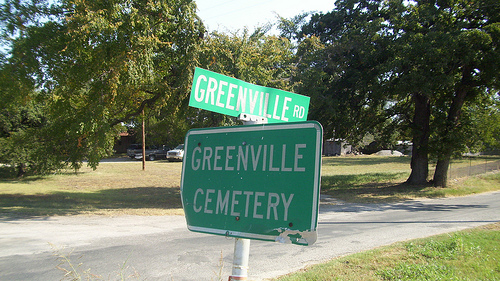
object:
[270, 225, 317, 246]
paint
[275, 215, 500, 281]
grassy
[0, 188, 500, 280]
sidewalk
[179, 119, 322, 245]
sign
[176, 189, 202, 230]
corner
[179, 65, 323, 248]
boards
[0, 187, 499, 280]
road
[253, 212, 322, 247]
ripped sign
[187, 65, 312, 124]
sign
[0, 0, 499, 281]
field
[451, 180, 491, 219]
ground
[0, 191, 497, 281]
street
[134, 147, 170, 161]
car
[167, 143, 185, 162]
car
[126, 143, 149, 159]
car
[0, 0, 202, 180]
green leaves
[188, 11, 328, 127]
green leaves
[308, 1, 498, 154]
green leaves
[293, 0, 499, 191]
tall tree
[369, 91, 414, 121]
branch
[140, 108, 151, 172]
pole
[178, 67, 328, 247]
text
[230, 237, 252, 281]
pole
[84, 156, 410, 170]
street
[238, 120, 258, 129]
pole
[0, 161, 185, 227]
lawn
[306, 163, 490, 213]
shadow